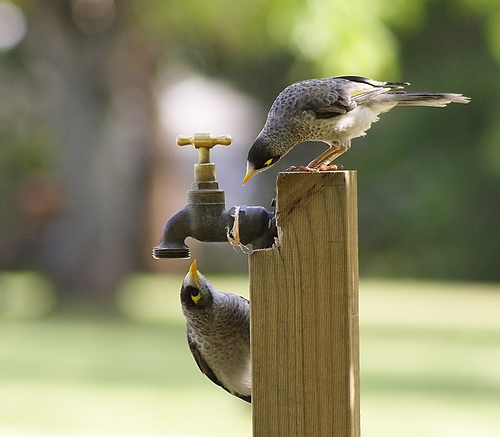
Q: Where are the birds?
A: On the faucet.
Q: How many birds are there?
A: 2.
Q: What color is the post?
A: Brown.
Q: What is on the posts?
A: Birds.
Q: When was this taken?
A: Daytime.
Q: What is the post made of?
A: Wood.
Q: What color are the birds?
A: Black and white.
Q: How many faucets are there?
A: 1.